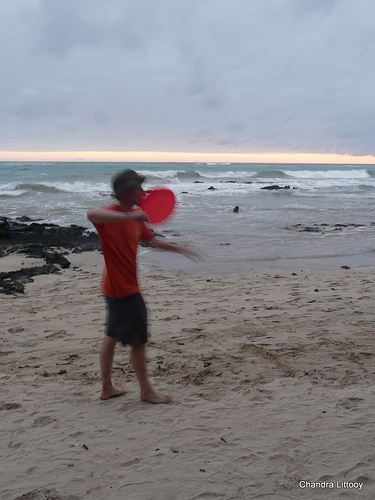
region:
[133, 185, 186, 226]
The frisbee is red.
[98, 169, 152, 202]
He is wearing a hat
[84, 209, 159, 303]
His shirt is red.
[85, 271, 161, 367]
His pants are grey.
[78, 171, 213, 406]
The man is standing in the sand.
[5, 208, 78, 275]
The rocks are black.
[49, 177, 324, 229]
The water is rocky.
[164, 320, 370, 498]
The sand is tan.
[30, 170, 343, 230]
THe waves are crashing on the shore.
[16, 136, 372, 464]
He is standing on the shore.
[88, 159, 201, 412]
a guy about to throw a frisbee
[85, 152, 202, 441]
a person playing on the beach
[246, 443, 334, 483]
footprints in the white sand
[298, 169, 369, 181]
white seafoam on the waves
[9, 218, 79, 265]
black rocks on the beach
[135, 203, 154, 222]
a hand grasping a red frisbee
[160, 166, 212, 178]
waves rolling towards the shore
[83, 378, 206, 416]
bare feet in the sand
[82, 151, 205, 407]
person wearing an orange shirt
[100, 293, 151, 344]
gray shorts covering thighs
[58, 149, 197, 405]
The man is playing frisbee on the beach.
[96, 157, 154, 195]
The man is wearing a hat on his head.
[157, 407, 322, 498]
Footprints are in the sand.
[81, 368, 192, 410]
The person does not have on any shoes.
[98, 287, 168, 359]
The man is wearing shorts.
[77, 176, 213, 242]
The man is holding a red frisbee.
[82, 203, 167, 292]
The man shirt is red.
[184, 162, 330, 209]
The water in the ocean looks choppy.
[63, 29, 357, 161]
The sky is full of clouds.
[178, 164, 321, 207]
A big wave on the borderline of the water.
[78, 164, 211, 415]
blurry dude @ ocean w/ frisbee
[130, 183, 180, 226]
frisbee is red, but if you look real close, in the blur it might be a balloon [unlikely]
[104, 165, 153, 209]
dude wears floppy hat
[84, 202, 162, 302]
dude wears orange t-shirt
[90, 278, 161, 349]
dude wears dark or black knee-length shorts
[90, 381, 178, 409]
dude is totally shoeless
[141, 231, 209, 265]
dude's left hand must be madly moving, cos it's blurry all over & seems to have been in at least three places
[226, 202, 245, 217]
is it a seal in the sea? or just a rounded rock?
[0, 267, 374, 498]
lots & lots of footprints in the sand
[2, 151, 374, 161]
a misty bar of yellowy sunlight between the heavy clouds & the unquiet ocean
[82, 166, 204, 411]
boy in short sleeve orange shirt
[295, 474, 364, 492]
watermark on bottom of photo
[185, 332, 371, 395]
footprints in the sand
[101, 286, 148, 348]
dark blue knee length shorts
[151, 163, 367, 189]
rough waves in ocean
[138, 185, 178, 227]
red frisbee about to be thrown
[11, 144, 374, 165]
clear sky on horizon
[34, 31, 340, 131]
overcast sky above boy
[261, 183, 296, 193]
rocks protruding from shore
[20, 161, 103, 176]
blue water in ocean